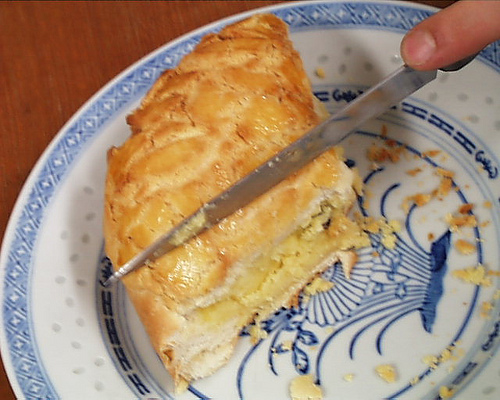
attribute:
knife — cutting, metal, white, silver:
[331, 60, 402, 138]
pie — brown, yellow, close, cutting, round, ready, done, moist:
[122, 53, 368, 355]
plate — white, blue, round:
[38, 101, 108, 245]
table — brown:
[4, 14, 100, 96]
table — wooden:
[2, 3, 469, 397]